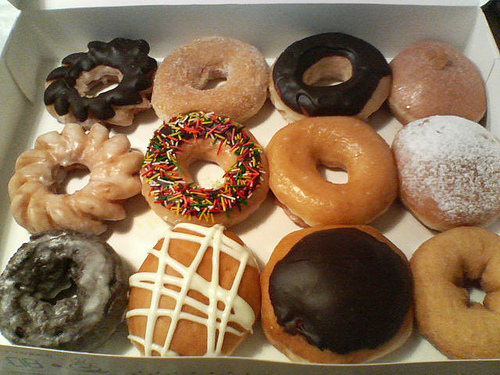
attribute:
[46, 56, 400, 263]
food — tasty, roasted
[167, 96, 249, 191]
item — sweet, tasty, oiled, circle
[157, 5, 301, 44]
plate — holding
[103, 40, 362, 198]
items — arranged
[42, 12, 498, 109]
box — cardboard, assorted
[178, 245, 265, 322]
lines — white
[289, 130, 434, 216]
donut — glazed, plain, white, shaped, old-fashioned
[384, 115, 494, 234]
sugar — powdered, coated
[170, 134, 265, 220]
sprinkles — arrayed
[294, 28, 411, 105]
donut — chocolate, topped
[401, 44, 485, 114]
donut — stuffed, creamfilled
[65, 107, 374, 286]
donuts — dozen, delicious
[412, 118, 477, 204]
donut — powdered, holeless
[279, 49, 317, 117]
chocolate — glazed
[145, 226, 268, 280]
stripes — zigzag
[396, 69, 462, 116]
pastry — filled